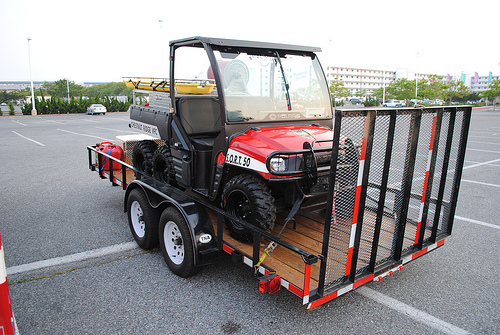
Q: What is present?
A: A truck.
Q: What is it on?
A: Wheels.